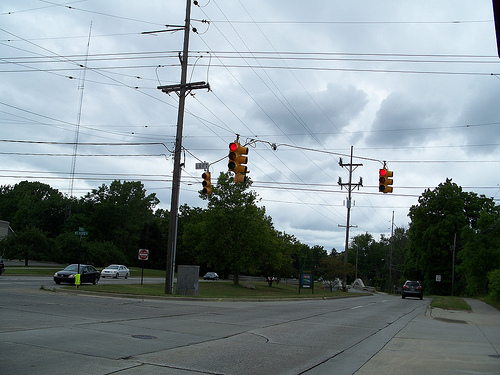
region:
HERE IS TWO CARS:
[49, 261, 136, 285]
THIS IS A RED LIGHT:
[226, 138, 251, 187]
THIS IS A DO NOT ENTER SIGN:
[135, 246, 151, 263]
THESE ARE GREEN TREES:
[185, 168, 498, 292]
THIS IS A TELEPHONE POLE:
[335, 143, 363, 293]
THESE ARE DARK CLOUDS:
[0, 0, 499, 251]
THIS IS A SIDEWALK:
[0, 293, 429, 373]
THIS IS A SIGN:
[298, 265, 316, 296]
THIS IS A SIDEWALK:
[354, 292, 497, 372]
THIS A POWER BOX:
[174, 259, 201, 301]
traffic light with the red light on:
[378, 166, 394, 192]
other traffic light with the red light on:
[226, 140, 242, 170]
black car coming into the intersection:
[55, 264, 100, 284]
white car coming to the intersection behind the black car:
[101, 263, 128, 276]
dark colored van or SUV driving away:
[402, 279, 422, 299]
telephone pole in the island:
[338, 145, 363, 292]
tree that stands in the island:
[192, 164, 297, 289]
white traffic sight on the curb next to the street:
[434, 275, 439, 300]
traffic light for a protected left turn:
[194, 163, 211, 196]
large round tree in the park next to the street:
[1, 179, 78, 267]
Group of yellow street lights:
[201, 123, 430, 228]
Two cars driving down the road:
[47, 253, 144, 303]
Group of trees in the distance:
[4, 149, 498, 331]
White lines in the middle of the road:
[341, 293, 415, 316]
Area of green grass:
[39, 254, 370, 314]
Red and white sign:
[124, 240, 156, 291]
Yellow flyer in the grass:
[68, 271, 90, 292]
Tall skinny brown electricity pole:
[332, 181, 367, 304]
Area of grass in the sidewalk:
[429, 275, 478, 337]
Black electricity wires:
[9, 15, 499, 136]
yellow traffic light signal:
[385, 161, 401, 206]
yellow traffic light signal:
[372, 158, 389, 197]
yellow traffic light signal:
[233, 135, 255, 195]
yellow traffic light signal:
[220, 127, 245, 183]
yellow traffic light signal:
[195, 163, 217, 205]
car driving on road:
[100, 254, 137, 286]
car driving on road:
[50, 252, 105, 289]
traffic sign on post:
[125, 241, 156, 291]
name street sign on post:
[67, 220, 98, 246]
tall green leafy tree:
[405, 158, 498, 318]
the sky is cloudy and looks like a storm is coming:
[2, 2, 495, 181]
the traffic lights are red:
[225, 139, 393, 196]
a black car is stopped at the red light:
[50, 258, 104, 287]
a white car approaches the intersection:
[99, 260, 131, 278]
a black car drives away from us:
[399, 275, 429, 300]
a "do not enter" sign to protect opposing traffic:
[135, 244, 151, 286]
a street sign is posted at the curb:
[69, 224, 89, 290]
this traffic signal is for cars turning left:
[192, 158, 214, 199]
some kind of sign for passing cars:
[296, 267, 316, 293]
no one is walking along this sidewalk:
[450, 285, 498, 326]